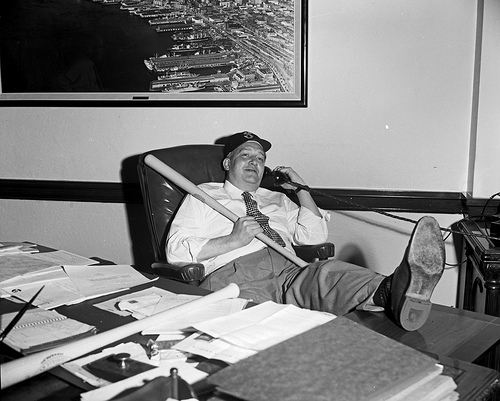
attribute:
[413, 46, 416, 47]
wall — light, dark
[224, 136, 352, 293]
man — sitting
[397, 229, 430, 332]
shoe — bottom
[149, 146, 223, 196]
bat — wood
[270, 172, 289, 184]
phone — wire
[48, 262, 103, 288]
papers — here, white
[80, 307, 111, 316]
desk — cluttered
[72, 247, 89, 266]
cober — here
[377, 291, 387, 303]
sock — black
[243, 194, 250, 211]
tie — polka dot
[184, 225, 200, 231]
shirt — white